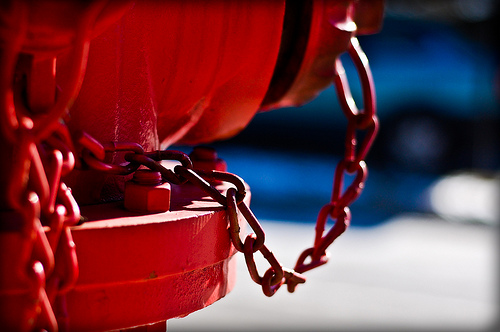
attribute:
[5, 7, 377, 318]
hydrant — right side, red, fire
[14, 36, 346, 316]
hydrant — emergency-used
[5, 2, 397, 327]
fire hydrant — red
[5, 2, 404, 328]
chain — red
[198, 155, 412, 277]
chain — hanging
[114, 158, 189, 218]
bolts — red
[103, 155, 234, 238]
nuts — red